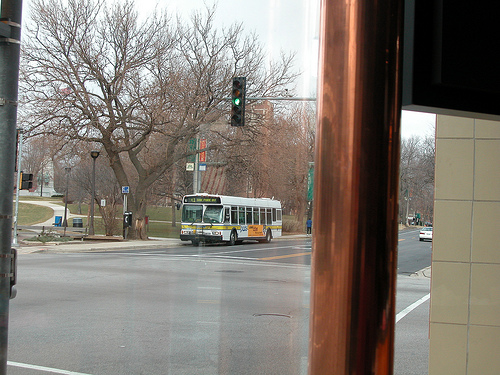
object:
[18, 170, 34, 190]
light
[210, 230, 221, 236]
light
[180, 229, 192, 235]
light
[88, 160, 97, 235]
pole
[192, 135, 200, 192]
pole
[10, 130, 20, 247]
pole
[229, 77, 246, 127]
stop sign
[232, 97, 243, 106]
light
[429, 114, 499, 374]
tile wall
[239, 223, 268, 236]
advertisement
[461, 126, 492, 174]
ground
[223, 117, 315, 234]
tree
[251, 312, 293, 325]
manhole cover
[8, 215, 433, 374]
pavement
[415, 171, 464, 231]
ground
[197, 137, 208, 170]
banner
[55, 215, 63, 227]
trash can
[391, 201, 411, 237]
ground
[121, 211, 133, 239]
booth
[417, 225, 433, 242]
car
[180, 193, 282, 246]
bus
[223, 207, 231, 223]
windows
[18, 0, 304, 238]
tree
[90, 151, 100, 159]
light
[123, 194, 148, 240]
trunk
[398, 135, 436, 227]
trees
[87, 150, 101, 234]
street lamp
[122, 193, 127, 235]
pole